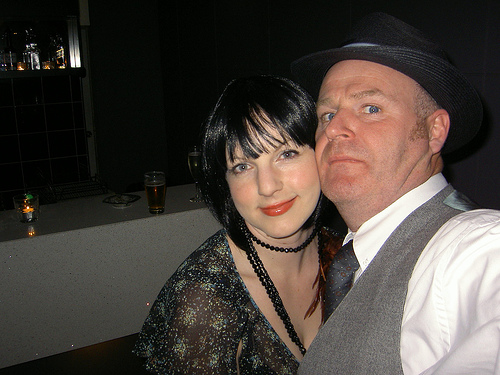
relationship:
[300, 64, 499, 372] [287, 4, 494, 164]
man wearing hat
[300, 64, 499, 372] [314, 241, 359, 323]
man wearing tie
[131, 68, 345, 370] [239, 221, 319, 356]
woman wearing necklace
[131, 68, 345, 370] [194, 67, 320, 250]
woman has hair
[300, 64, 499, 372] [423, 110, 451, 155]
man has ear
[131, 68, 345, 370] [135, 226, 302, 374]
woman wearing shirt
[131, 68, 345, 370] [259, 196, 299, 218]
woman has lips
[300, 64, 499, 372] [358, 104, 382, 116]
man has eye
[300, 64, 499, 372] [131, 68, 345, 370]
man and woman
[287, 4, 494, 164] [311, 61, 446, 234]
hat on head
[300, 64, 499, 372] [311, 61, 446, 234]
man has head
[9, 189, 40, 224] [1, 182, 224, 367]
candle on bar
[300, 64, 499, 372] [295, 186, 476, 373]
man wears vest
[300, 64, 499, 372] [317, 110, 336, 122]
man has eye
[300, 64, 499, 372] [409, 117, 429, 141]
man has sideburn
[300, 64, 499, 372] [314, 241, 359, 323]
man wears tie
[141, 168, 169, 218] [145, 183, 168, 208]
glass of beer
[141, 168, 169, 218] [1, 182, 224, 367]
glass on bar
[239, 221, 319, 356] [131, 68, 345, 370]
necklace on woman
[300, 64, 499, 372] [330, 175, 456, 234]
man has neck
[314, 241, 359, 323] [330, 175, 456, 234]
tie on neck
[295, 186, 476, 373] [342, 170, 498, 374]
vest on shirt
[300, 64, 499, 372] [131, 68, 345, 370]
man close to woman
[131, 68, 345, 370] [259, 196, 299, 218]
woman wearing lips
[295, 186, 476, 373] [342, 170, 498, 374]
vest with shirt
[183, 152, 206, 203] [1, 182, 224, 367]
drink on bar